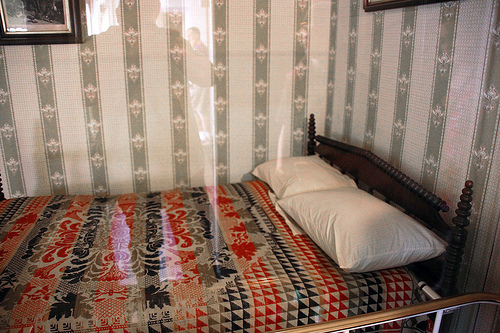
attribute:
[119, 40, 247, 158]
wallpaper — striped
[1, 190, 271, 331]
pattern — floral, circular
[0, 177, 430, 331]
bedspread — colorful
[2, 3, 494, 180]
wallpaper — striped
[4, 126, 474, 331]
bed — made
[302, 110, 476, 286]
frame — large, wooden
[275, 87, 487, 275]
headboard — dark brown, wooden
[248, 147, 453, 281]
pillows — white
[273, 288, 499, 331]
frame — wood, metal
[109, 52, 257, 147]
wallpaper — green, cream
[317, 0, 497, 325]
wallpaper — striped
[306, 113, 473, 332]
head board — brown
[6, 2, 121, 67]
picture — framed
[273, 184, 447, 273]
pillow — white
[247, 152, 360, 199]
pillow — white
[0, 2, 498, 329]
drape — sheer